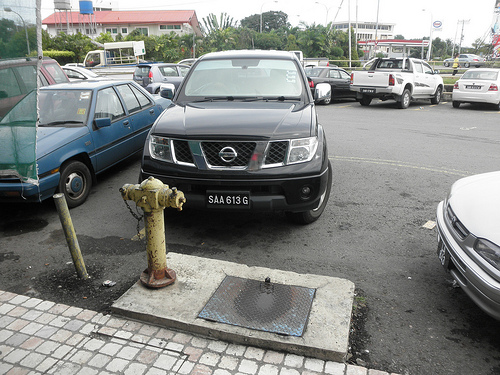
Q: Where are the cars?
A: The parking lot.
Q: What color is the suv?
A: Black.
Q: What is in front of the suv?
A: A hydrant.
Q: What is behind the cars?
A: A building.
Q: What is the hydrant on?
A: Concrete.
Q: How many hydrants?
A: 1.